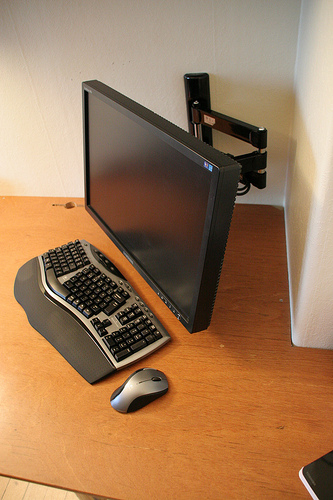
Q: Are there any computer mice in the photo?
A: Yes, there is a computer mouse.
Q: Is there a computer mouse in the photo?
A: Yes, there is a computer mouse.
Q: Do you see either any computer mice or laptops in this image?
A: Yes, there is a computer mouse.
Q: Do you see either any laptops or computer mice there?
A: Yes, there is a computer mouse.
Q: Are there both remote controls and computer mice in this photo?
A: No, there is a computer mouse but no remote controls.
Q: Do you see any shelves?
A: No, there are no shelves.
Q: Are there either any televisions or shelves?
A: No, there are no shelves or televisions.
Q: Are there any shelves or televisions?
A: No, there are no shelves or televisions.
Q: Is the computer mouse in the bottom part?
A: Yes, the computer mouse is in the bottom of the image.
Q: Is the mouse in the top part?
A: No, the mouse is in the bottom of the image.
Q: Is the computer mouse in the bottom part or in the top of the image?
A: The computer mouse is in the bottom of the image.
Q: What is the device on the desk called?
A: The device is a computer mouse.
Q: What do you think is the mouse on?
A: The mouse is on the desk.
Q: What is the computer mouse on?
A: The mouse is on the desk.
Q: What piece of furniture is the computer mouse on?
A: The computer mouse is on the desk.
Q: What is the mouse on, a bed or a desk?
A: The mouse is on a desk.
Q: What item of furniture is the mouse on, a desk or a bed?
A: The mouse is on a desk.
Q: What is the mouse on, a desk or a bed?
A: The mouse is on a desk.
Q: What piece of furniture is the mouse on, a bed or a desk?
A: The mouse is on a desk.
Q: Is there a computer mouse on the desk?
A: Yes, there is a computer mouse on the desk.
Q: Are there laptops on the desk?
A: No, there is a computer mouse on the desk.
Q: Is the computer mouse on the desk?
A: Yes, the computer mouse is on the desk.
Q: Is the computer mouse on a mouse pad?
A: No, the computer mouse is on the desk.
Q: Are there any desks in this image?
A: Yes, there is a desk.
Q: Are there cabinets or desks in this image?
A: Yes, there is a desk.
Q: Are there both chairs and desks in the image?
A: No, there is a desk but no chairs.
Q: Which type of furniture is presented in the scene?
A: The furniture is a desk.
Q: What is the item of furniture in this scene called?
A: The piece of furniture is a desk.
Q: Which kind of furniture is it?
A: The piece of furniture is a desk.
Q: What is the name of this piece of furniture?
A: This is a desk.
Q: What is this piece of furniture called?
A: This is a desk.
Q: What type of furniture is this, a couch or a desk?
A: This is a desk.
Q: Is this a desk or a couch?
A: This is a desk.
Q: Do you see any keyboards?
A: Yes, there is a keyboard.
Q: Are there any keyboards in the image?
A: Yes, there is a keyboard.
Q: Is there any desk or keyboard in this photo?
A: Yes, there is a keyboard.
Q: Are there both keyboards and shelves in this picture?
A: No, there is a keyboard but no shelves.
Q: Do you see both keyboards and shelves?
A: No, there is a keyboard but no shelves.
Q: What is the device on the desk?
A: The device is a keyboard.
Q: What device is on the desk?
A: The device is a keyboard.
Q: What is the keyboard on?
A: The keyboard is on the desk.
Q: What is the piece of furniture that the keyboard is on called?
A: The piece of furniture is a desk.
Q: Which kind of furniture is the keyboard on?
A: The keyboard is on the desk.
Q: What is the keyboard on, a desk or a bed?
A: The keyboard is on a desk.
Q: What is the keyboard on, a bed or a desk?
A: The keyboard is on a desk.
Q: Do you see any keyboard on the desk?
A: Yes, there is a keyboard on the desk.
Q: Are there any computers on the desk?
A: No, there is a keyboard on the desk.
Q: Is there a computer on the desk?
A: No, there is a keyboard on the desk.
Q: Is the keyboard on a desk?
A: Yes, the keyboard is on a desk.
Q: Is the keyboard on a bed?
A: No, the keyboard is on a desk.